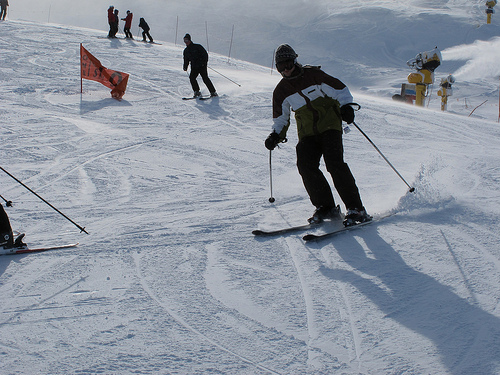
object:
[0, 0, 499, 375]
snow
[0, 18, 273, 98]
hill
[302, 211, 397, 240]
board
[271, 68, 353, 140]
jacket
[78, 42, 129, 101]
flag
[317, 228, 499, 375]
shadow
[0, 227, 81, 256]
skate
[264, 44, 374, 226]
man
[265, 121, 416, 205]
skis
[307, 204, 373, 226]
snow boots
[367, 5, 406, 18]
jackson mingus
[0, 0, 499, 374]
photo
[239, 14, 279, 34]
detail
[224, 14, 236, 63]
pole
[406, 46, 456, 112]
machines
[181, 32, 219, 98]
skier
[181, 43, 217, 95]
black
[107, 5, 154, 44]
four skiers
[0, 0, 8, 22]
lone skier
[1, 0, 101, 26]
distance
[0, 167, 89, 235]
back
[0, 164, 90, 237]
ski pole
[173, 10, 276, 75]
rods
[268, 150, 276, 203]
ski pole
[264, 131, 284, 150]
hand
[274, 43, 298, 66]
hat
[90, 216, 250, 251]
ski tracks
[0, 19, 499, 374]
slope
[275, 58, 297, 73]
goggles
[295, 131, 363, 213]
pants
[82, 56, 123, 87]
writing